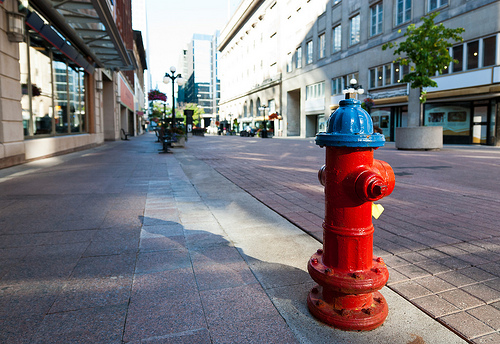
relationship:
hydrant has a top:
[309, 91, 398, 331] [314, 92, 387, 148]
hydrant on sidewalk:
[309, 91, 398, 331] [3, 124, 465, 342]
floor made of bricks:
[178, 129, 499, 343] [419, 246, 458, 269]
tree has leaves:
[380, 13, 466, 102] [427, 33, 430, 38]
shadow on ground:
[139, 216, 316, 320] [3, 124, 465, 342]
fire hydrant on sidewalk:
[309, 91, 398, 331] [3, 124, 465, 342]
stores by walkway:
[8, 36, 147, 149] [3, 124, 465, 342]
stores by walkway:
[215, 95, 499, 146] [178, 129, 499, 343]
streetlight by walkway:
[161, 65, 184, 145] [3, 124, 465, 342]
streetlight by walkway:
[258, 100, 271, 134] [178, 129, 499, 343]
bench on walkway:
[156, 128, 177, 155] [3, 124, 465, 342]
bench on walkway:
[121, 126, 133, 141] [3, 124, 465, 342]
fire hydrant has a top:
[309, 91, 398, 331] [314, 92, 387, 148]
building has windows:
[225, 3, 499, 149] [293, 15, 499, 111]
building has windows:
[2, 2, 148, 168] [18, 27, 98, 142]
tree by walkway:
[380, 13, 466, 102] [178, 129, 499, 343]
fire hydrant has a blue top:
[309, 91, 398, 331] [314, 92, 387, 148]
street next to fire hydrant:
[178, 129, 499, 343] [309, 91, 398, 331]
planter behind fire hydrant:
[396, 126, 444, 151] [309, 91, 398, 331]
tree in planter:
[380, 13, 466, 102] [396, 126, 444, 151]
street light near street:
[161, 65, 184, 145] [178, 129, 499, 343]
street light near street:
[258, 100, 271, 134] [178, 129, 499, 343]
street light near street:
[227, 110, 235, 131] [178, 129, 499, 343]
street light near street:
[161, 100, 169, 133] [178, 129, 499, 343]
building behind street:
[176, 31, 221, 133] [178, 129, 499, 343]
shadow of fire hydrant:
[139, 216, 316, 320] [309, 91, 398, 331]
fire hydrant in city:
[309, 91, 398, 331] [0, 1, 498, 343]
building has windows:
[176, 31, 221, 133] [181, 35, 218, 128]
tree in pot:
[380, 13, 466, 102] [396, 126, 444, 151]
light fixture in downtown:
[161, 65, 184, 145] [0, 1, 498, 343]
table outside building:
[192, 125, 207, 139] [225, 3, 499, 149]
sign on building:
[425, 105, 472, 139] [225, 3, 499, 149]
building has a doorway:
[2, 2, 148, 168] [101, 70, 118, 145]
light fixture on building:
[6, 11, 26, 44] [2, 2, 148, 168]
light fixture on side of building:
[6, 11, 26, 44] [2, 2, 148, 168]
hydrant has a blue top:
[309, 91, 398, 331] [314, 92, 387, 148]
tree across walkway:
[380, 13, 466, 102] [178, 129, 499, 343]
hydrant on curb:
[309, 91, 398, 331] [174, 147, 455, 343]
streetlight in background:
[161, 65, 184, 145] [2, 2, 498, 164]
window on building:
[332, 23, 344, 54] [225, 3, 499, 149]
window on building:
[350, 11, 361, 47] [225, 3, 499, 149]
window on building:
[369, 2, 383, 37] [225, 3, 499, 149]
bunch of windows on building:
[293, 15, 499, 111] [225, 3, 499, 149]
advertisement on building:
[445, 105, 472, 143] [225, 3, 499, 149]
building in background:
[176, 31, 221, 133] [2, 2, 498, 164]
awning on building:
[146, 88, 169, 103] [2, 2, 148, 168]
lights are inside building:
[395, 61, 404, 84] [225, 3, 499, 149]